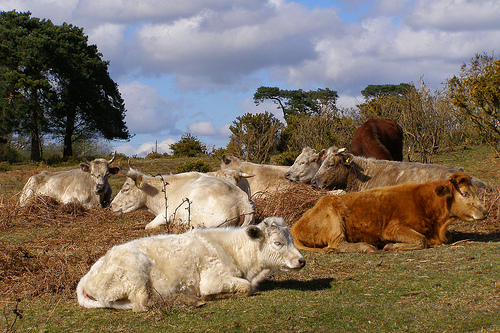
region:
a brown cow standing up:
[347, 117, 410, 157]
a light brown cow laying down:
[290, 172, 484, 253]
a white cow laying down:
[72, 214, 304, 312]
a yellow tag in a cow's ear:
[346, 155, 351, 163]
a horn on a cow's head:
[106, 149, 118, 164]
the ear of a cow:
[242, 224, 266, 244]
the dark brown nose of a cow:
[296, 257, 310, 267]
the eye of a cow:
[272, 238, 282, 247]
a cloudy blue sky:
[0, 2, 497, 155]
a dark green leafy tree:
[48, 23, 130, 159]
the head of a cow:
[232, 172, 336, 280]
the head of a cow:
[223, 199, 302, 286]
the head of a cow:
[424, 159, 496, 231]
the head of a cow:
[262, 199, 319, 284]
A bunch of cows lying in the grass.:
[16, 114, 496, 317]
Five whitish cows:
[18, 154, 306, 315]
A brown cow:
[288, 167, 488, 254]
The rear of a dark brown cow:
[346, 115, 411, 162]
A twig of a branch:
[154, 170, 196, 233]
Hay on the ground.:
[7, 205, 76, 306]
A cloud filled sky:
[1, 0, 498, 155]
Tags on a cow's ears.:
[316, 149, 353, 166]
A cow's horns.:
[77, 150, 120, 165]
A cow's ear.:
[243, 223, 265, 245]